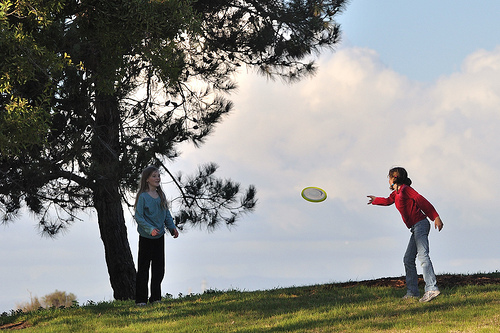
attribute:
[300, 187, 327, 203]
frisbee — thrown, flying, white, round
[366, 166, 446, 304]
girl — young, playing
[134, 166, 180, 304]
girl — standing, young, playing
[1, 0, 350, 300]
tree — large, tall, green, pine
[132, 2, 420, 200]
cloud — white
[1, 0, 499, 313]
sky — blue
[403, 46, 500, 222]
cloud — white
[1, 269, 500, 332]
grass — dry, green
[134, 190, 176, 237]
shirt — blue, long-sleeved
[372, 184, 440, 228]
shirt — red, long-sleeved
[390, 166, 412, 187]
hair — brown, long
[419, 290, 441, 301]
shoe — white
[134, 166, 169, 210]
hair — long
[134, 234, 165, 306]
pants — dark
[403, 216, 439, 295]
pants — light-colored